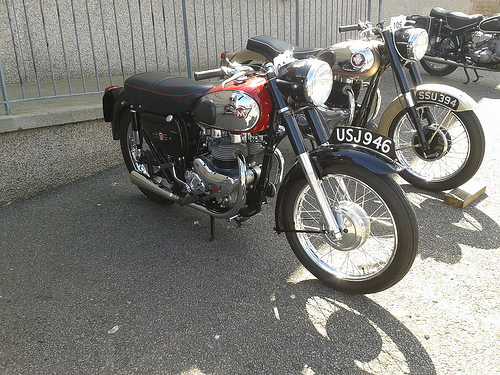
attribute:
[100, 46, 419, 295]
bike — black, parked, red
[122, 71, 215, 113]
seat — black, padded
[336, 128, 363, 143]
letters — white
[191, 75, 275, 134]
gas tank — red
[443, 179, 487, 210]
block — yellow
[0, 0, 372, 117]
railing — metal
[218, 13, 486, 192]
motorcycle — gold, black, gold colored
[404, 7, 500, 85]
motorcycle — black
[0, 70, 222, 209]
ramp — concrete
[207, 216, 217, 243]
kick stand — down